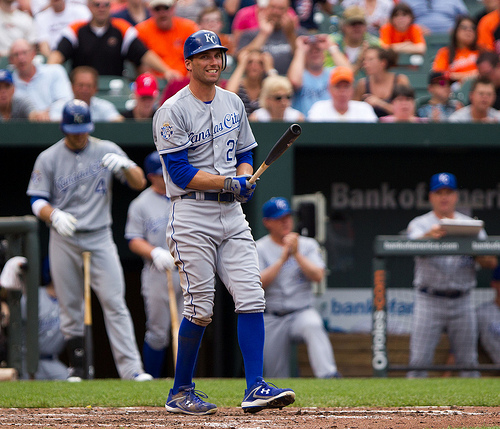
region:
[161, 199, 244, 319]
Man wearing gray pants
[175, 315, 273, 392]
Man wearing blue socks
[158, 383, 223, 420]
Man wearing blue sneakers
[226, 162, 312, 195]
Man wearing blue gloves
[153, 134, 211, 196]
Man with long sleeve shirts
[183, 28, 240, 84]
Man wearing a blue helmet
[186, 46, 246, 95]
man with a smile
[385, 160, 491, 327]
coach holding a clipboard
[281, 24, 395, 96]
crowd watching a baseball game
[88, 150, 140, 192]
Man wearing white gloves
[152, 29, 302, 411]
Player going up to bat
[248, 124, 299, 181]
Bat is black and yellow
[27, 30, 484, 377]
People are playing baseball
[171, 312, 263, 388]
The socks are blue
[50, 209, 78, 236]
The glove is white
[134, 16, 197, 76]
The shirt is orange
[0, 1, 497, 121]
Crowd watching the game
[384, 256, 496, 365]
The mesh is dark colored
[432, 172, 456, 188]
Hat is blue and white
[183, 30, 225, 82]
The man is smiling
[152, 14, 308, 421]
baseball player holding a bat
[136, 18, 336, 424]
baseball player wearing grey gloves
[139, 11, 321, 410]
baseball player wearing grey uniform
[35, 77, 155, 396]
baseball player wearing white gloves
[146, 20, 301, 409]
baseball player wearing blue socks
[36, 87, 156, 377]
baseball player with bat leaning on him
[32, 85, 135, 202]
baseball player wearing blue helmet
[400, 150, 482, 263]
man wearing blue hat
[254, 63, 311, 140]
woman wearing dark sunglasses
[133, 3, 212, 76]
man wearing orange shirt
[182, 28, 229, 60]
blue helmet on a baseball player's head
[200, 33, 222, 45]
white print on a baseball players helmet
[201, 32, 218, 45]
white print on a blue helmet reading KC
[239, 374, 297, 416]
blue and white cleats on a baseball player's foot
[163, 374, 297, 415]
blue and white cleats on a baseball player's feet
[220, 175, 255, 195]
blue and gray gloves on a baseball player's hand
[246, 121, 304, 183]
baseball bat in a player's hands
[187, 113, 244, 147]
blue text on a gray jersey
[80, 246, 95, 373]
baseball bat on a player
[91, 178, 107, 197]
the number four printed on a gray jersey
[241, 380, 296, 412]
A blue shoe with white bottom.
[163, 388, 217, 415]
A blue shoe with a blue shoelace.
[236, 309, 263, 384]
A blue sock.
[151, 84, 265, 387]
A blue based uniform.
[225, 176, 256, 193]
A blue glove.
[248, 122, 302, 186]
A baseball bat.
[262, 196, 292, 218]
A blue baseball cap.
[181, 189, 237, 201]
A dark colored belt.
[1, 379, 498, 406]
A green field.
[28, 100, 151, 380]
A man in the background.